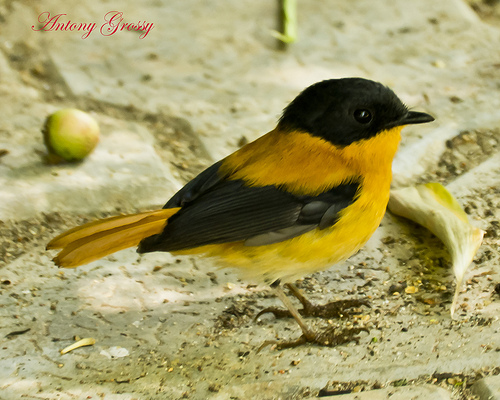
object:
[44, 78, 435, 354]
bird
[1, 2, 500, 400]
ground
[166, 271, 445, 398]
rock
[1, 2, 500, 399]
outside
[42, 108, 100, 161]
fruit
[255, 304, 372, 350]
feet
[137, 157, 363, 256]
feathers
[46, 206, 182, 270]
feather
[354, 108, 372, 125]
eye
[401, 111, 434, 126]
beak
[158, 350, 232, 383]
seed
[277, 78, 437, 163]
head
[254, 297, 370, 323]
foot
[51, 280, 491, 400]
area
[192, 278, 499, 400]
dirt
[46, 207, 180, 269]
tail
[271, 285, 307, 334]
leg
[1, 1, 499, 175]
background